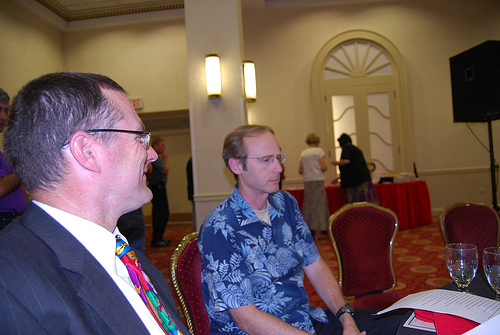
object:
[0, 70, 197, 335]
man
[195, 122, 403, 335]
man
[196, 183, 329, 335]
shirt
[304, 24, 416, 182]
doorway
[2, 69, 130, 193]
hair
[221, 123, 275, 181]
hair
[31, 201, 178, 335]
shirt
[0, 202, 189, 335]
jacket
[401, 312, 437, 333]
paper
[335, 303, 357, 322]
watch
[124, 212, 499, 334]
carpet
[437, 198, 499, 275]
chair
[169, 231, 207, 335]
frame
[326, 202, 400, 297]
frame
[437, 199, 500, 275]
frame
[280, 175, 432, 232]
table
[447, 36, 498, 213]
speaker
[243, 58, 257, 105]
light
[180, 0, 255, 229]
pillar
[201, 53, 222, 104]
sconce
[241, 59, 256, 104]
sconce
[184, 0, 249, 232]
wall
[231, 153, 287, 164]
eyeglasses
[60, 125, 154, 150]
eyeglasses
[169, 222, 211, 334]
chair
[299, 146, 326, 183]
shirt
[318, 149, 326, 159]
sleeve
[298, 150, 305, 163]
sleeve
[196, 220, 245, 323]
sleeve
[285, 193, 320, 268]
sleeve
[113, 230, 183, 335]
tie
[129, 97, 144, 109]
exit sign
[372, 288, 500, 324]
sheet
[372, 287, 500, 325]
paper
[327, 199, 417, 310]
chair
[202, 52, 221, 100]
light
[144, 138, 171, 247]
man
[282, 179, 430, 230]
table cloth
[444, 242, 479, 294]
glass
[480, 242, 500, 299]
glass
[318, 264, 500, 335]
table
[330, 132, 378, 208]
woman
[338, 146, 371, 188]
shirt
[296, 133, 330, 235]
woman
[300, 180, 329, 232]
skirt